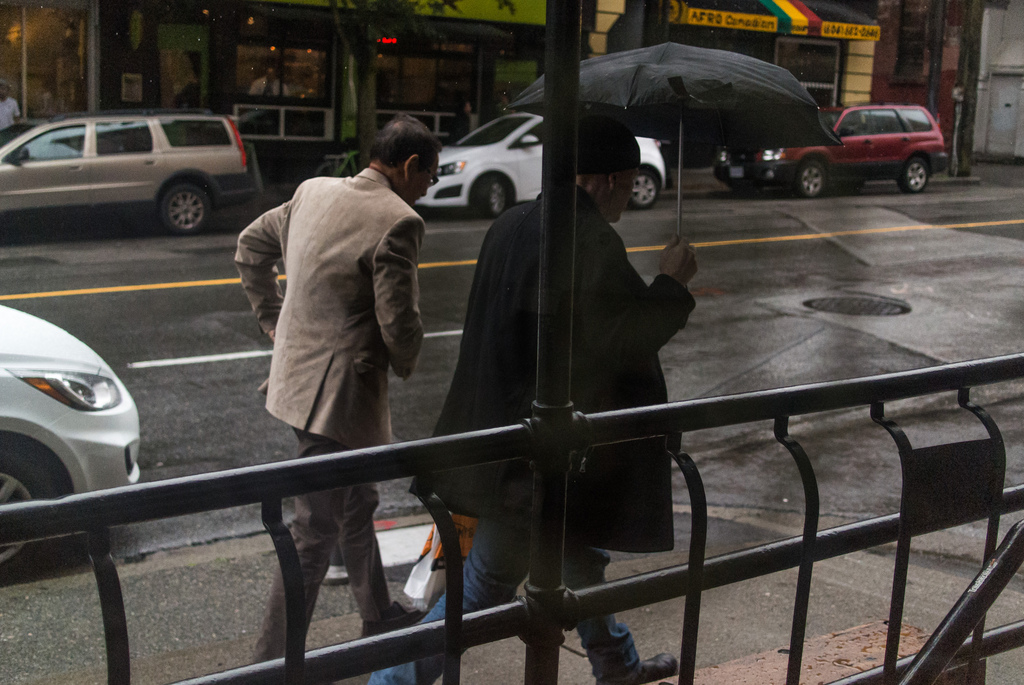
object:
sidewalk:
[9, 385, 1009, 681]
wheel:
[161, 191, 215, 233]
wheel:
[2, 435, 89, 576]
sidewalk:
[120, 536, 879, 681]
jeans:
[368, 515, 649, 680]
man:
[379, 116, 700, 683]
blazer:
[239, 168, 426, 453]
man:
[247, 117, 420, 649]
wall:
[61, 39, 740, 191]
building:
[93, 0, 627, 191]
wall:
[154, 26, 568, 307]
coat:
[409, 180, 699, 554]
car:
[417, 106, 675, 213]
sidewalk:
[258, 459, 865, 676]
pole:
[668, 121, 685, 237]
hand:
[662, 236, 703, 289]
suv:
[713, 96, 940, 198]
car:
[0, 307, 155, 562]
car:
[6, 110, 260, 234]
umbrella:
[513, 41, 844, 144]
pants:
[228, 430, 425, 676]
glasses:
[424, 167, 448, 191]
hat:
[566, 107, 640, 162]